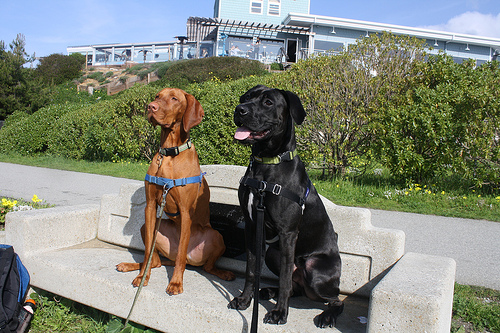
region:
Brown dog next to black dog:
[114, 79, 239, 294]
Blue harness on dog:
[145, 170, 211, 192]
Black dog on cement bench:
[223, 81, 346, 328]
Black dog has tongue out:
[225, 80, 343, 332]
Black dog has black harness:
[220, 85, 336, 326]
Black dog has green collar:
[230, 80, 331, 330]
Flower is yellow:
[30, 185, 45, 200]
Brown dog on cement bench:
[115, 85, 235, 296]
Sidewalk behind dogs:
[0, 145, 497, 290]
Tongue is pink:
[231, 127, 251, 142]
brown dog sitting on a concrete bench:
[112, 85, 233, 301]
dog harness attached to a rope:
[140, 167, 215, 282]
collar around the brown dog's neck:
[155, 135, 191, 150]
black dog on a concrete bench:
[221, 80, 343, 325]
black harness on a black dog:
[236, 170, 321, 330]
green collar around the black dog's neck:
[245, 145, 291, 165]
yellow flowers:
[0, 190, 45, 205]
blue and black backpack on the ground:
[0, 237, 35, 327]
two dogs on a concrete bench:
[114, 81, 356, 325]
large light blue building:
[65, 1, 495, 63]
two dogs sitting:
[87, 35, 417, 331]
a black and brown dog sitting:
[114, 61, 392, 328]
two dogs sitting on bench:
[104, 64, 386, 331]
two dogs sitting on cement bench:
[23, 49, 428, 299]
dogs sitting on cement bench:
[108, 46, 410, 331]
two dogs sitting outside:
[17, 36, 432, 331]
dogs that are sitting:
[72, 61, 483, 331]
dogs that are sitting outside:
[102, 54, 415, 321]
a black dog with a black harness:
[207, 62, 369, 330]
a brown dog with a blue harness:
[109, 60, 236, 265]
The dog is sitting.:
[103, 72, 235, 306]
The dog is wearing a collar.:
[96, 75, 238, 309]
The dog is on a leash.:
[115, 74, 215, 301]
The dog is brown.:
[83, 78, 238, 303]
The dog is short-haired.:
[96, 70, 244, 306]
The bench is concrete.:
[0, 145, 459, 331]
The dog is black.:
[217, 72, 354, 332]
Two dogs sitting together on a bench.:
[50, 80, 361, 331]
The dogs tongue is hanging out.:
[218, 67, 352, 331]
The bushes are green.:
[0, 35, 498, 195]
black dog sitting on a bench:
[231, 73, 366, 331]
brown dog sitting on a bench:
[134, 64, 219, 299]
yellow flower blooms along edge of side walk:
[1, 183, 41, 224]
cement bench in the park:
[4, 163, 486, 332]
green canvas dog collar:
[239, 145, 314, 169]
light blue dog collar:
[137, 161, 220, 198]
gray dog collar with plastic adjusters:
[139, 131, 206, 172]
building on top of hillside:
[73, 26, 234, 78]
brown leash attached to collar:
[128, 191, 170, 328]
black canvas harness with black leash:
[232, 162, 307, 252]